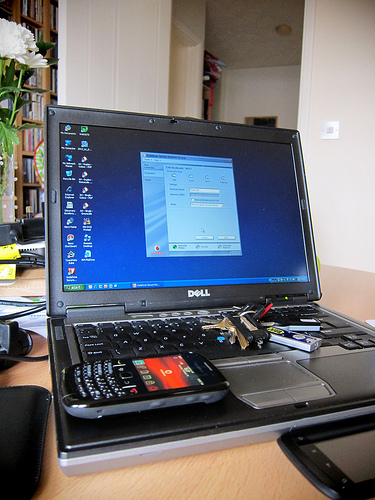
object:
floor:
[321, 267, 365, 293]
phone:
[58, 350, 230, 422]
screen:
[58, 121, 308, 292]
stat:
[320, 120, 340, 140]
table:
[215, 457, 287, 500]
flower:
[0, 16, 48, 73]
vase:
[0, 152, 19, 228]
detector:
[275, 23, 291, 38]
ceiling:
[206, 0, 301, 70]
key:
[199, 300, 273, 352]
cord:
[0, 352, 51, 363]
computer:
[44, 105, 375, 467]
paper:
[0, 243, 21, 283]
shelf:
[9, 0, 57, 219]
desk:
[33, 429, 323, 498]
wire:
[0, 251, 45, 266]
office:
[0, 0, 375, 500]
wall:
[318, 21, 373, 80]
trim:
[0, 17, 58, 197]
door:
[169, 29, 198, 118]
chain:
[259, 323, 320, 354]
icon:
[60, 124, 95, 286]